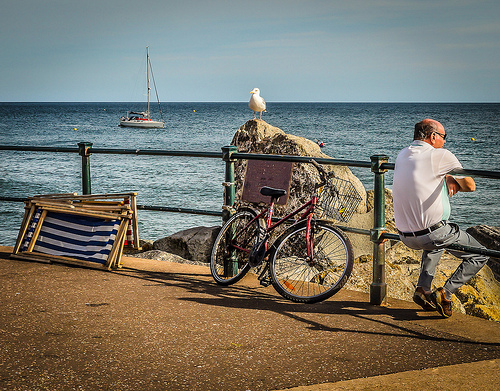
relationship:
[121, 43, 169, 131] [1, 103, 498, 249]
boat in ocean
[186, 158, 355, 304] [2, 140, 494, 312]
bicycle on fence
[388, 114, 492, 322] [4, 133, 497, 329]
man on fence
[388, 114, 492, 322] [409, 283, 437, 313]
man wearing shoe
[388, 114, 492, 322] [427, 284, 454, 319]
man wearing shoe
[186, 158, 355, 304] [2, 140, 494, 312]
bicycle leaning against fence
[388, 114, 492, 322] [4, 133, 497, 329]
man sitting on fence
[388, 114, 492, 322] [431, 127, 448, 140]
man wearing glasses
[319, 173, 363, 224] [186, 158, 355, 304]
basket attached to bicycle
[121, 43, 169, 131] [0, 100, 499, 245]
boat floating in water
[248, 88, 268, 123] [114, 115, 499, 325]
bird sitting on rock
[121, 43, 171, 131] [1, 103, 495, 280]
boat floating in ocean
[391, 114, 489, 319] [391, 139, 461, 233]
man wearing shirt